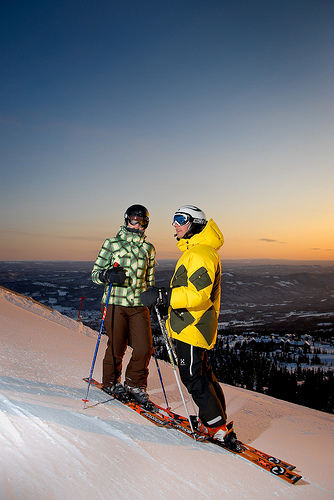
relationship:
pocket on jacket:
[187, 267, 213, 292] [166, 216, 222, 352]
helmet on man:
[174, 203, 206, 221] [138, 203, 226, 425]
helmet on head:
[174, 203, 206, 221] [170, 204, 206, 240]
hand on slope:
[94, 263, 133, 285] [3, 283, 332, 499]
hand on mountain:
[138, 283, 176, 310] [3, 281, 332, 497]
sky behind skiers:
[29, 26, 326, 192] [91, 199, 156, 402]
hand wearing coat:
[94, 263, 133, 285] [166, 217, 225, 349]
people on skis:
[139, 202, 231, 443] [82, 375, 301, 485]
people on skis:
[91, 202, 156, 405] [66, 360, 199, 442]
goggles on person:
[162, 209, 189, 227] [147, 197, 247, 458]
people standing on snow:
[139, 202, 231, 443] [10, 286, 331, 486]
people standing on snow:
[91, 202, 156, 405] [10, 286, 331, 486]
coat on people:
[95, 227, 157, 309] [91, 202, 156, 405]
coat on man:
[164, 217, 226, 351] [135, 201, 238, 443]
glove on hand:
[140, 284, 175, 303] [138, 283, 176, 310]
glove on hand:
[100, 267, 132, 286] [94, 263, 133, 285]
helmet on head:
[116, 198, 153, 224] [117, 198, 154, 240]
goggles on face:
[170, 209, 189, 227] [166, 207, 191, 239]